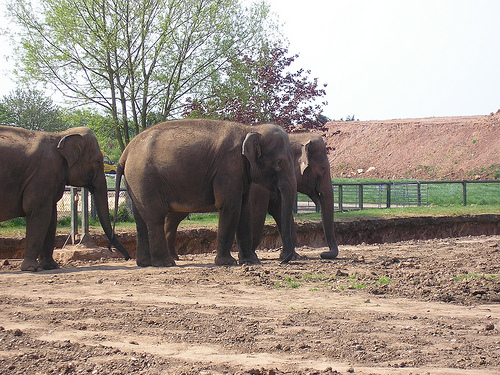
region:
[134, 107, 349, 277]
2 elephants standing together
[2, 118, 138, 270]
one elephant slightly behind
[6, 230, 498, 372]
3 elephants standing in dirt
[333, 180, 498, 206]
gray metal fence behind elephants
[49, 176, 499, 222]
patches of grass surround fence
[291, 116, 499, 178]
dirt piled into a mound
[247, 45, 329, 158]
tree with purplish red leaves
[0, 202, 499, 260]
small cylindrical ditch behind elephants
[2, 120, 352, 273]
3 elephants facing right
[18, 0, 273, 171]
tree with small yellowish green leaves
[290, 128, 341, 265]
right hand side elephant head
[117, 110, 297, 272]
middle brown elephant with hair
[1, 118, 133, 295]
last elephant behind other two elephants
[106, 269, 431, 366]
dry soil on ground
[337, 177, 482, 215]
green pasture beyond fence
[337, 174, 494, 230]
elephant enclosure fence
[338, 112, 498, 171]
dirt hill in background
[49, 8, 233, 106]
tall leafy green tree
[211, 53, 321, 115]
small reddish cherry tree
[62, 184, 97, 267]
two metal posts behind third elephant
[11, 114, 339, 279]
three elephants standing on dirt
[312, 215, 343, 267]
elephant trunk on ground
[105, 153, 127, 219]
elephant tail on rear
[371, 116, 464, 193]
hill of dirt above grass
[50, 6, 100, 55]
green leaves on trees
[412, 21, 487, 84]
pale blue of daytime sky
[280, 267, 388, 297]
patches of grass in dirt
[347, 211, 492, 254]
long hole in dirt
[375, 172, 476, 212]
poles and rail on fence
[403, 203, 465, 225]
grass on side of dirt bank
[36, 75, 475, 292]
three elephants together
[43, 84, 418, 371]
three elephants outside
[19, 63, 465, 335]
three elephants standing in dirt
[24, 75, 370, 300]
three elephants fenced in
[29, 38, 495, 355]
elephants standing in dirt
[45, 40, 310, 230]
elephants that are standing together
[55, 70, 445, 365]
elephants are astanding together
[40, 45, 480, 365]
elephants that are fenced in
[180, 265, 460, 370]
a dirt field outside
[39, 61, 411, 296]
elephants that are outside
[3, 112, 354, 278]
Three elephants are looking the same direction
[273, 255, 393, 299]
Small patches of green grass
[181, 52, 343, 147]
Tree appears red and green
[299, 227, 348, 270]
Elephants trunk is on the ground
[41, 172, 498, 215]
Fence behind the elephants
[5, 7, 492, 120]
Sky looks grey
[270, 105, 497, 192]
Dirt hill in the background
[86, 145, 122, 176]
Yellow vehicle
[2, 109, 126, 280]
Elephant is behind the others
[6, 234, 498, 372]
Ground under elephants is dirt